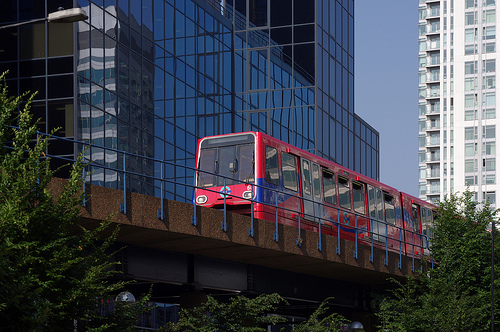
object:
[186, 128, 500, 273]
train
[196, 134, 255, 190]
windshield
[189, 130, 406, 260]
car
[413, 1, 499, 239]
building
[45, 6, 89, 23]
light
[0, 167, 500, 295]
tracks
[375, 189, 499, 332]
trees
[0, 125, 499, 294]
overpass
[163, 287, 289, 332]
trees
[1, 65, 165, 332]
trees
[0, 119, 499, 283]
rails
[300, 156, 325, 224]
doors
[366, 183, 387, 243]
doors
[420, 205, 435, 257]
doors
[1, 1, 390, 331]
building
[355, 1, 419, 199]
sky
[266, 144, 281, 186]
windows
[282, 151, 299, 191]
windows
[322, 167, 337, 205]
windows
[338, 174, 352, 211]
windows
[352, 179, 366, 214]
windows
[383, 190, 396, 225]
windows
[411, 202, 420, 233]
windows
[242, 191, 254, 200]
lights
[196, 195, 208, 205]
lights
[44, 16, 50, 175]
pole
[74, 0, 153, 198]
reflection